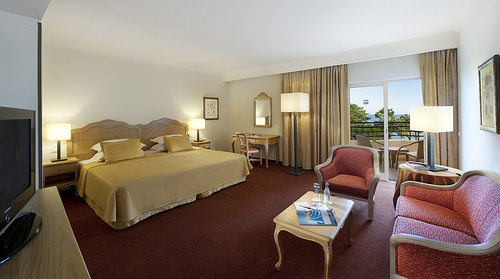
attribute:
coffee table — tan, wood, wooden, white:
[272, 188, 355, 278]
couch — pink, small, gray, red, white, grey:
[387, 169, 499, 278]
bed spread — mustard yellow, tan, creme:
[76, 145, 253, 223]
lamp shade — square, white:
[279, 91, 310, 114]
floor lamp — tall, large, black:
[280, 90, 310, 177]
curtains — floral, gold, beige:
[278, 63, 348, 171]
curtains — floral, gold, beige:
[416, 47, 458, 169]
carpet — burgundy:
[59, 154, 397, 278]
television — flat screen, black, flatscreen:
[1, 105, 41, 263]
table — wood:
[1, 183, 92, 278]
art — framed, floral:
[476, 52, 499, 136]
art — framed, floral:
[202, 94, 221, 121]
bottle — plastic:
[322, 181, 332, 203]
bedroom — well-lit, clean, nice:
[0, 0, 499, 278]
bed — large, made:
[65, 117, 252, 229]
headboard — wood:
[68, 115, 190, 162]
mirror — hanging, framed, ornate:
[254, 99, 270, 128]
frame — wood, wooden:
[253, 90, 274, 129]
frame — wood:
[476, 51, 499, 136]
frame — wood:
[201, 95, 219, 121]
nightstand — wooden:
[43, 155, 79, 195]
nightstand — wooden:
[194, 136, 211, 150]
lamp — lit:
[44, 119, 72, 164]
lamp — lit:
[191, 117, 206, 143]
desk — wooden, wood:
[229, 130, 280, 169]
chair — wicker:
[391, 138, 426, 168]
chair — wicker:
[355, 131, 384, 167]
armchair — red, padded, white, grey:
[314, 142, 380, 223]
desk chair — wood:
[234, 132, 263, 170]